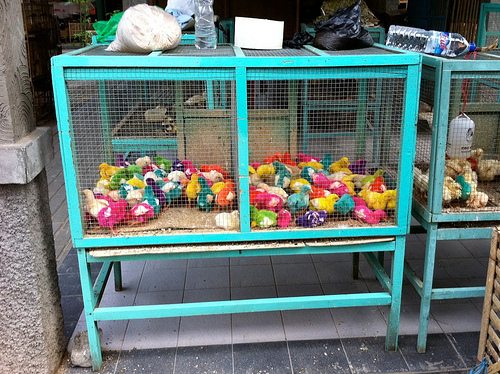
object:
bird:
[80, 188, 109, 221]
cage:
[47, 40, 428, 373]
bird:
[212, 209, 242, 232]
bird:
[294, 208, 328, 230]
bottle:
[383, 23, 477, 59]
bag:
[311, 0, 375, 52]